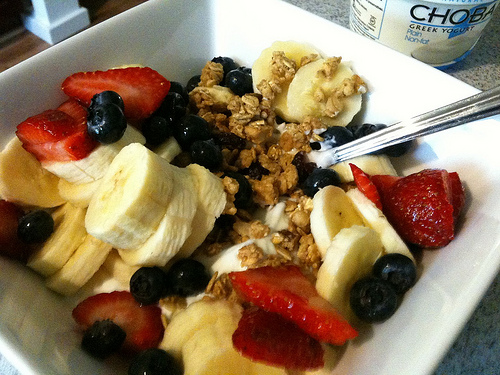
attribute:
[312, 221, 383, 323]
banana — cut, ripe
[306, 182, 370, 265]
banana — cut, ripe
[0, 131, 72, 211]
banana — cut, ripe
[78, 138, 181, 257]
banana — cut, ripe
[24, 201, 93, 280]
banana — cut, ripe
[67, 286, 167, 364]
strawberry — cut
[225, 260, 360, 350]
strawberry — cut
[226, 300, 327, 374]
strawberry — cut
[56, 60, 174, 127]
strawberry — cut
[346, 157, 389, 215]
strawberry — cut